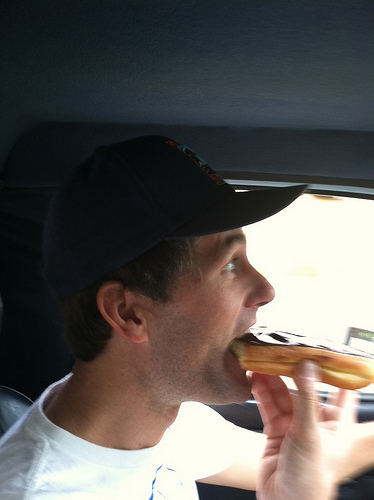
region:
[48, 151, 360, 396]
Man eating a doughnut.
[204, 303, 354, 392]
Icing on the doughnut.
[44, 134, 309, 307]
Hat on the man.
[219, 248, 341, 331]
light behind the man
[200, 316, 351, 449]
Man's hand with doughnut.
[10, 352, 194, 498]
Man in a white t-shirt.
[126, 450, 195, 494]
Design on the shirt.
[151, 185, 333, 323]
Eye of the man.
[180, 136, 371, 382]
Window on the vehicle.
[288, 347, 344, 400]
Fingernail on the man's hand.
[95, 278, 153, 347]
the ear of person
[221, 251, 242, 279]
an eye of a person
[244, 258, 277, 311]
the nose of a person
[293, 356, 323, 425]
the thumb of a person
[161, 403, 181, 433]
the adams apple of a man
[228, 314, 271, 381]
a mouth taking a bite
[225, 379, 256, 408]
a chin of a person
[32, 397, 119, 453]
a collar of a white shirt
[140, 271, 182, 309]
the sideburns of a man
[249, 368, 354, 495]
the hand of a person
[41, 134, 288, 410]
the head of a man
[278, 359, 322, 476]
the thumb of a man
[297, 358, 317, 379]
the thumb nail of a man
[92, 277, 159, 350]
the ear of a man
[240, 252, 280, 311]
the nose of a man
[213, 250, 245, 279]
the eye of a man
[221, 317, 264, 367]
the mouth of a man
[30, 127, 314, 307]
a black baseball cap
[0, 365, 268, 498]
a white tee shirt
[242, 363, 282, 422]
the finger of a man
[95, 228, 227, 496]
a man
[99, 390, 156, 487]
a man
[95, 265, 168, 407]
a man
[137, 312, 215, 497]
a man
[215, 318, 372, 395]
the man is eating an eclair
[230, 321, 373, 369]
the eclair has chocolate icing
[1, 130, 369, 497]
the man is driving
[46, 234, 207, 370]
the man has short hair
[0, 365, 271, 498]
the man is wearing a white t-shirt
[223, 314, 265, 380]
the man is biting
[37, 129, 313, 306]
the man has a black hat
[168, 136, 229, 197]
the hat has a logo on it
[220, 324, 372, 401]
the man is holding the eclair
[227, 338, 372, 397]
the eclair is golden brown